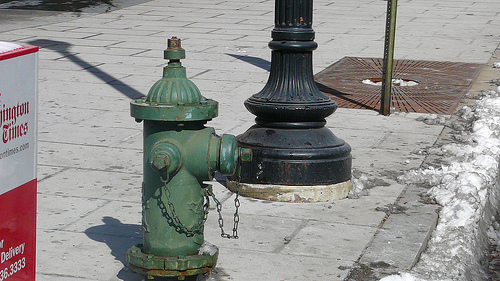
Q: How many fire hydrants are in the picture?
A: One.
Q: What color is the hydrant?
A: Green.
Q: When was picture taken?
A: Sunset.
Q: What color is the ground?
A: Grey.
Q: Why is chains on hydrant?
A: Security.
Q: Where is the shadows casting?
A: Ground.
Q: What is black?
A: Pole.